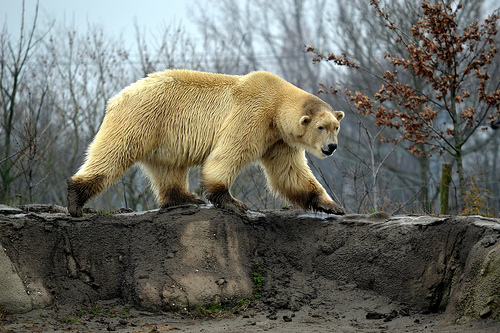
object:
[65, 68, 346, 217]
polar bear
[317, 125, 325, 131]
eye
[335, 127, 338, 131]
eye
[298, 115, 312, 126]
ear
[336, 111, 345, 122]
ear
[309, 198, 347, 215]
paw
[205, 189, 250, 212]
paw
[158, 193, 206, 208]
paw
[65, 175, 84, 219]
paw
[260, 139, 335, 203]
leg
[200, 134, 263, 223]
leg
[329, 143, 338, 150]
nose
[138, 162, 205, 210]
leg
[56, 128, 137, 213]
leg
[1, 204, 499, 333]
dirt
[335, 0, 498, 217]
tree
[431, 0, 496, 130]
leaves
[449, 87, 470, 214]
trunk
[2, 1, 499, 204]
background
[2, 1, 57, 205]
tree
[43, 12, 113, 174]
tree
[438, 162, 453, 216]
pole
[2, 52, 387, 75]
power lines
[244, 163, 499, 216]
fence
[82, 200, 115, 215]
grass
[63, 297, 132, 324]
grass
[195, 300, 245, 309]
grass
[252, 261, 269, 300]
grass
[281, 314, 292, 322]
rock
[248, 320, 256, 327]
rock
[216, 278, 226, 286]
rock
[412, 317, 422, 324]
rock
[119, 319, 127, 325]
rock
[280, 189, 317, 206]
fur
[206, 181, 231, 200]
fur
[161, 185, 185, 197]
fur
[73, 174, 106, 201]
fur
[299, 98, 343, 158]
head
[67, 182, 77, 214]
bottom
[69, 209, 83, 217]
toes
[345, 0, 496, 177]
branch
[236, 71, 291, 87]
hump